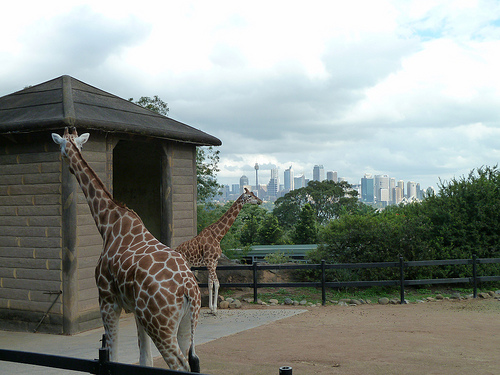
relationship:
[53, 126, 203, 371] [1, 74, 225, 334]
giraffe near house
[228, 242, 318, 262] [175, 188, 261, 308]
train by animal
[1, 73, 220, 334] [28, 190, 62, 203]
house made of brick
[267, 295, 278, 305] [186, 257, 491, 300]
rock below fence